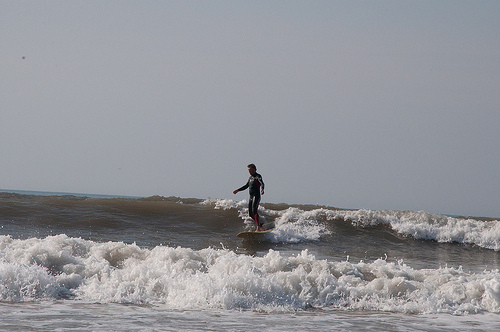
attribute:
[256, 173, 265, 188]
arm — out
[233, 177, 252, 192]
arm — out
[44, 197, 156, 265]
water — choppy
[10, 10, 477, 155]
sky — gloomy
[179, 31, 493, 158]
clouds — white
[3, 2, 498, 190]
sky — blue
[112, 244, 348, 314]
foam — white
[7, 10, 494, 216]
cloud — white, blue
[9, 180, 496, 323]
ocean — clear blue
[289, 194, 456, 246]
waves — large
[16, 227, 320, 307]
waves — ocean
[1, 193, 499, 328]
water — turbulent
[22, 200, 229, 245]
water — zealous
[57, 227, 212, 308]
water — powerful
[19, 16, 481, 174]
sky — blue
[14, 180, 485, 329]
water — wavy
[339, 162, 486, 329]
water — white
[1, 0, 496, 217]
clouds — white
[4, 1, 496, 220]
sky — blue, clear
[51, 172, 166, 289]
water — gray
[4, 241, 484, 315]
foam — white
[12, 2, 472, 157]
clouds — white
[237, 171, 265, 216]
outfit — black, white